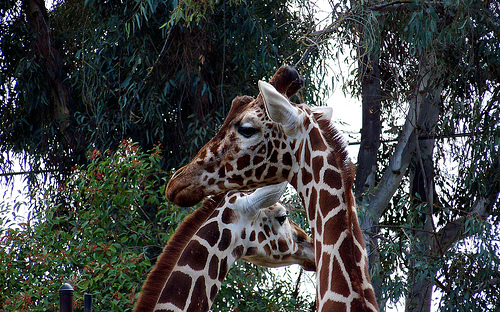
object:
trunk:
[352, 61, 499, 312]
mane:
[135, 193, 224, 312]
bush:
[0, 138, 311, 312]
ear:
[313, 107, 334, 124]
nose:
[172, 168, 183, 179]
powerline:
[0, 130, 500, 175]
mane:
[313, 114, 356, 201]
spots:
[330, 256, 349, 298]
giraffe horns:
[258, 65, 304, 106]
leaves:
[146, 10, 234, 108]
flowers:
[0, 138, 273, 312]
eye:
[271, 201, 298, 232]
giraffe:
[165, 65, 380, 312]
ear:
[245, 181, 286, 209]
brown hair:
[269, 67, 304, 97]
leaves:
[346, 2, 498, 76]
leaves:
[1, 1, 100, 88]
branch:
[380, 187, 492, 299]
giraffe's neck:
[290, 152, 382, 312]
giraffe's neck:
[135, 226, 235, 312]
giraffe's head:
[189, 183, 318, 271]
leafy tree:
[0, 0, 500, 312]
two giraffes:
[132, 64, 382, 311]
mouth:
[169, 183, 190, 203]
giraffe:
[131, 182, 316, 312]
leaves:
[71, 162, 154, 256]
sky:
[0, 0, 500, 312]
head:
[165, 65, 341, 209]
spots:
[176, 240, 208, 271]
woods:
[0, 0, 500, 312]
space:
[377, 213, 484, 273]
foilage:
[0, 6, 184, 225]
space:
[2, 140, 90, 231]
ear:
[259, 80, 297, 124]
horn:
[256, 65, 306, 104]